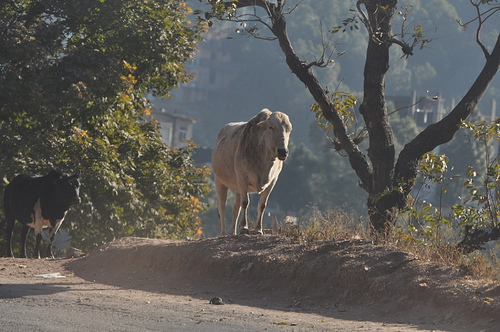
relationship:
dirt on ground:
[33, 259, 108, 323] [0, 231, 482, 326]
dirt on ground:
[175, 239, 270, 302] [0, 237, 499, 329]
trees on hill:
[202, 2, 489, 234] [154, 147, 499, 245]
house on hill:
[343, 89, 471, 159] [154, 147, 499, 245]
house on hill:
[145, 106, 192, 171] [154, 147, 499, 245]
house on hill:
[166, 0, 257, 110] [154, 147, 499, 245]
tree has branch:
[233, 4, 498, 268] [394, 41, 499, 192]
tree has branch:
[233, 4, 498, 268] [358, 7, 399, 176]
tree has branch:
[233, 4, 498, 268] [245, 6, 372, 179]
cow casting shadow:
[203, 105, 295, 236] [5, 270, 73, 295]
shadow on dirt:
[5, 270, 73, 295] [0, 229, 499, 329]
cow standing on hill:
[203, 105, 295, 236] [59, 226, 499, 330]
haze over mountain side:
[154, 1, 483, 244] [157, 22, 485, 234]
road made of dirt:
[1, 251, 498, 329] [0, 229, 499, 329]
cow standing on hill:
[211, 108, 296, 233] [78, 230, 495, 327]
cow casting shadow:
[3, 167, 100, 269] [3, 280, 99, 305]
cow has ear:
[192, 107, 297, 242] [253, 117, 268, 131]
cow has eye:
[211, 108, 296, 233] [264, 122, 276, 132]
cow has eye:
[183, 90, 384, 241] [285, 124, 293, 134]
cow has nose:
[204, 105, 313, 235] [276, 144, 293, 171]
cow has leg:
[207, 102, 295, 247] [251, 188, 274, 237]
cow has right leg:
[207, 102, 295, 247] [237, 185, 251, 235]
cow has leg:
[203, 105, 295, 236] [237, 188, 251, 235]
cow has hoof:
[185, 74, 318, 249] [252, 227, 262, 235]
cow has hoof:
[185, 74, 318, 249] [240, 226, 252, 236]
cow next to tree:
[213, 106, 288, 241] [243, 0, 498, 248]